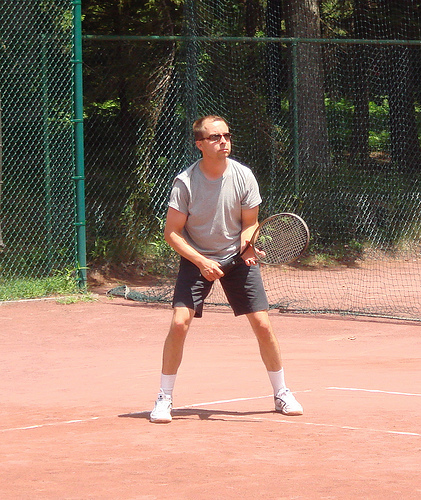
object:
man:
[148, 113, 301, 424]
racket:
[199, 211, 311, 283]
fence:
[84, 0, 419, 327]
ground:
[319, 104, 345, 158]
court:
[0, 276, 417, 496]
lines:
[0, 382, 411, 451]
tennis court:
[0, 295, 421, 500]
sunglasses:
[198, 132, 232, 142]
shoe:
[275, 389, 302, 417]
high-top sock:
[268, 367, 286, 394]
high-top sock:
[161, 374, 175, 395]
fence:
[0, 0, 87, 305]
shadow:
[118, 403, 290, 424]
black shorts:
[172, 251, 268, 316]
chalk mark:
[0, 383, 331, 432]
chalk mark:
[326, 383, 420, 398]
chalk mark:
[186, 407, 420, 437]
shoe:
[150, 392, 175, 424]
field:
[0, 288, 420, 497]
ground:
[73, 364, 334, 452]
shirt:
[167, 156, 263, 264]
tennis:
[197, 213, 312, 281]